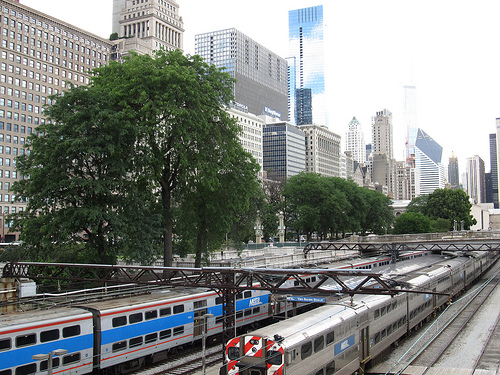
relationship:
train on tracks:
[226, 261, 465, 368] [442, 261, 497, 372]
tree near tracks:
[45, 66, 260, 273] [442, 261, 497, 372]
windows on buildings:
[9, 20, 113, 104] [40, 8, 419, 218]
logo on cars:
[249, 294, 266, 311] [3, 285, 264, 366]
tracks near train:
[442, 261, 497, 372] [226, 261, 465, 368]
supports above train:
[12, 260, 389, 301] [226, 261, 465, 368]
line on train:
[110, 290, 271, 346] [3, 285, 264, 366]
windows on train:
[119, 312, 190, 342] [3, 285, 264, 366]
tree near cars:
[45, 66, 260, 273] [3, 285, 264, 366]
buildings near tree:
[40, 8, 419, 218] [45, 66, 260, 273]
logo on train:
[249, 294, 266, 311] [3, 285, 264, 366]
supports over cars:
[12, 260, 389, 301] [3, 285, 264, 366]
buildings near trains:
[40, 8, 419, 218] [7, 240, 469, 370]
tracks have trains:
[442, 261, 497, 372] [7, 240, 469, 370]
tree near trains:
[45, 66, 260, 273] [7, 240, 469, 370]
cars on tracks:
[3, 285, 264, 366] [442, 261, 497, 372]